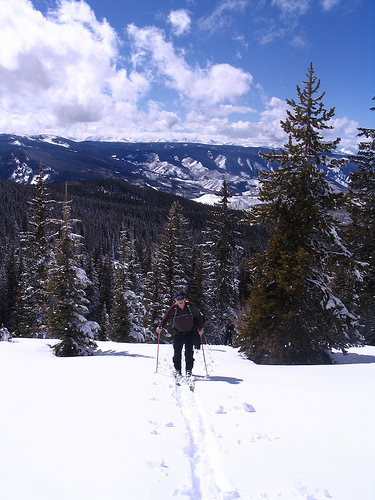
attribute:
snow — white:
[52, 372, 332, 486]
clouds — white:
[3, 1, 374, 155]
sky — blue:
[3, 1, 367, 155]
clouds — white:
[161, 39, 262, 110]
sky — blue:
[139, 4, 350, 74]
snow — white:
[49, 381, 181, 461]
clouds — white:
[194, 21, 315, 87]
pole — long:
[152, 324, 160, 375]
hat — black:
[167, 294, 201, 302]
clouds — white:
[47, 38, 96, 75]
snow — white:
[0, 336, 373, 497]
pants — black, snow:
[169, 331, 194, 377]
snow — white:
[0, 360, 373, 495]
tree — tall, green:
[235, 60, 368, 371]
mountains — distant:
[106, 130, 244, 179]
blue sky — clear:
[237, 0, 372, 123]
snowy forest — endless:
[2, 108, 352, 316]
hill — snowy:
[0, 336, 374, 498]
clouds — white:
[20, 30, 219, 157]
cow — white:
[176, 61, 259, 105]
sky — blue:
[0, 19, 355, 148]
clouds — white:
[14, 10, 176, 132]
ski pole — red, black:
[152, 327, 161, 372]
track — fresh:
[174, 398, 189, 414]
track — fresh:
[203, 424, 223, 443]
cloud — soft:
[117, 116, 163, 140]